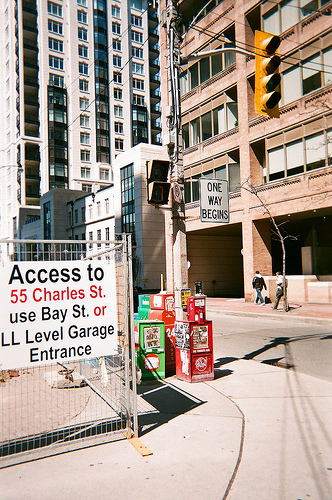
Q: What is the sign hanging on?
A: A metal fence.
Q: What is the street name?
A: Charles st.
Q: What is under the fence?
A: A sidewalk.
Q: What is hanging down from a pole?
A: Traffic light.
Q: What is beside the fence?
A: A green paper holder.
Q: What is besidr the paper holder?
A: A metal pole.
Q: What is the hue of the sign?
A: Black and white.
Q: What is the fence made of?
A: Gray metal.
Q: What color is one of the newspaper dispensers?
A: Red.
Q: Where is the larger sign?
A: On the fence.